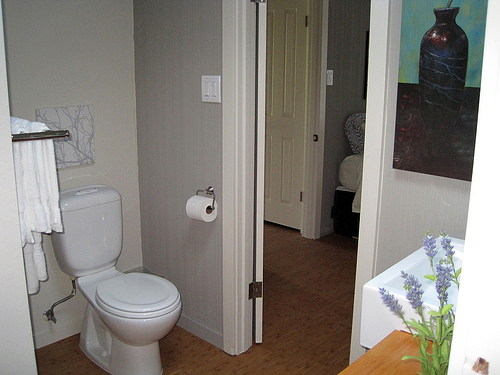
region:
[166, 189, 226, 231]
White Toilet tissue in on the wall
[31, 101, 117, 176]
Picture of the outline of gray trees on wall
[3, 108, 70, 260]
White Towel is hanging on the wall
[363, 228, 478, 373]
Purple flowers is on the wooden table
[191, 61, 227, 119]
White light switch on the wall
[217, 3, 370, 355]
White Bathroom door is wide open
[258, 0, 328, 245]
White door outside bathroom is closed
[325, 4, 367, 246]
Wall outside bathroom is gray in color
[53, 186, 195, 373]
Bathroom toilet has the lid down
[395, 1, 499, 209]
Large Bathroom painting is hanging on the wall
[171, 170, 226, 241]
a hanging toilet paper holder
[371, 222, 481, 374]
a purple floral arrangement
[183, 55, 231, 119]
a white lightswitch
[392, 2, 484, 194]
artwork hanging on a bathroom wall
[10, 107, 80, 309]
white towels hanging on a towel bar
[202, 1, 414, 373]
a bathroom doorway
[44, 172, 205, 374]
a white toilet stool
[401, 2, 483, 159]
a painting of a vase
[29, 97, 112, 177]
a small piece of square artwork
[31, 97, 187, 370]
a piece of artwork hanging above a toilet stool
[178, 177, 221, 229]
toilet paper on a wall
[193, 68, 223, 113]
light switches on a wall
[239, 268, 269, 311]
a hinge on a door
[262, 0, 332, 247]
a door in a room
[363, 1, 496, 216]
a picture on a wall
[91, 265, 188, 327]
a white toilet seat on a toilet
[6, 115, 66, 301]
white towels on a rack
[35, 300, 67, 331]
water shut off valve for a toilet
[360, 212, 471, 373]
flowers on a brown table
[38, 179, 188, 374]
a toilet in a bathroom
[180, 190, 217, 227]
a roll of toilet paper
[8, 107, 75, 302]
two white towels hanging up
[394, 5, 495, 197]
a picture on the wall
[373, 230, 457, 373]
purple lilac flowers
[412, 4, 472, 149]
a brown vase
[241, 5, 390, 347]
an open bathroom door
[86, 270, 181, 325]
a closed toilet seat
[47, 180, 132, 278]
a small toilet tank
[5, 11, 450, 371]
a white bathroom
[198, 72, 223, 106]
two light switches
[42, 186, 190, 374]
a white toilet in a bathroom with the lid closed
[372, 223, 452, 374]
a small spray of lavender on the table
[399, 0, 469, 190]
a painting of a vase on the wall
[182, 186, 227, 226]
a roll of toilet paper in a holder on the wall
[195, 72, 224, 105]
a white light switch on the wall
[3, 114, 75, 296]
several white towels hanging on a towel rack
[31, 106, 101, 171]
a small abstract painting on the wall behind the toilet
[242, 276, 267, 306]
a metal hinge on the door frame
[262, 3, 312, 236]
a white door in the next room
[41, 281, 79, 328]
silver metal plumbing in the back of the toilet